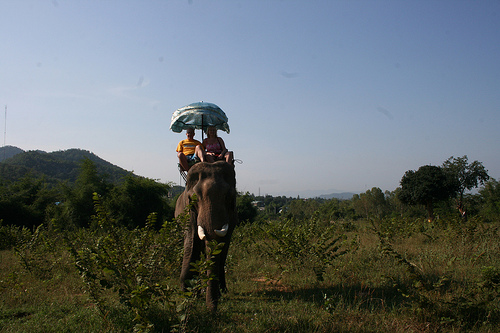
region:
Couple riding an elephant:
[117, 100, 322, 292]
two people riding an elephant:
[175, 97, 259, 277]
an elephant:
[188, 172, 258, 288]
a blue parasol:
[172, 95, 232, 129]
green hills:
[3, 128, 138, 186]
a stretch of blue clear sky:
[98, 14, 478, 88]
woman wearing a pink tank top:
[203, 127, 235, 158]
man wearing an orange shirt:
[175, 123, 206, 156]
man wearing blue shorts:
[178, 152, 198, 169]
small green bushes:
[272, 217, 428, 296]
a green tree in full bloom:
[389, 165, 461, 214]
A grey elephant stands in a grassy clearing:
[147, 146, 285, 323]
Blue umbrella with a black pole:
[165, 82, 243, 182]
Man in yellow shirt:
[172, 125, 203, 168]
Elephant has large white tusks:
[163, 157, 258, 312]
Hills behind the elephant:
[6, 127, 469, 227]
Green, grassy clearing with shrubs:
[13, 149, 483, 317]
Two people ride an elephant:
[146, 102, 260, 307]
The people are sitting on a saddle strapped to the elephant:
[168, 149, 245, 177]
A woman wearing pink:
[198, 117, 241, 177]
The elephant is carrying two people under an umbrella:
[156, 87, 263, 309]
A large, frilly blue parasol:
[167, 100, 232, 136]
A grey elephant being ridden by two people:
[174, 158, 239, 311]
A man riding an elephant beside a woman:
[173, 126, 205, 171]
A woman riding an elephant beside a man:
[201, 125, 233, 167]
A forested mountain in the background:
[1, 147, 148, 193]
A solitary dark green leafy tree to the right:
[396, 162, 462, 221]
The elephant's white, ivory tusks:
[196, 223, 231, 240]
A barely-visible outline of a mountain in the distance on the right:
[316, 190, 361, 200]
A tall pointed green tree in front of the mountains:
[73, 157, 111, 230]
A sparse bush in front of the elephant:
[79, 188, 226, 331]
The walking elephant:
[170, 161, 242, 314]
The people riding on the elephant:
[166, 125, 237, 168]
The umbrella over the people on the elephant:
[167, 96, 233, 136]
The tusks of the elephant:
[192, 221, 231, 242]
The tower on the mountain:
[0, 96, 8, 145]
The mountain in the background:
[1, 141, 498, 228]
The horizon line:
[1, 143, 499, 197]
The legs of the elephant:
[173, 226, 230, 312]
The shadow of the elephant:
[223, 269, 432, 314]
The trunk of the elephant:
[200, 227, 225, 282]